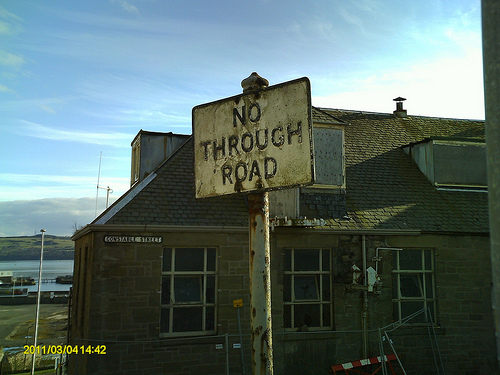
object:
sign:
[104, 233, 160, 244]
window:
[162, 243, 215, 335]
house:
[70, 107, 500, 371]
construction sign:
[332, 348, 402, 375]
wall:
[86, 231, 498, 375]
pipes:
[376, 304, 446, 371]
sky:
[0, 2, 484, 240]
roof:
[88, 104, 490, 233]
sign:
[190, 75, 318, 200]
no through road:
[197, 103, 303, 185]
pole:
[247, 188, 273, 375]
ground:
[0, 362, 500, 372]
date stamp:
[23, 340, 78, 357]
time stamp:
[81, 341, 107, 356]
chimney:
[392, 96, 407, 115]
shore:
[0, 271, 70, 298]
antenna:
[76, 147, 117, 214]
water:
[1, 258, 78, 293]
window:
[436, 144, 487, 185]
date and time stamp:
[24, 345, 108, 358]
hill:
[0, 232, 75, 260]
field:
[0, 303, 69, 345]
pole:
[32, 229, 46, 375]